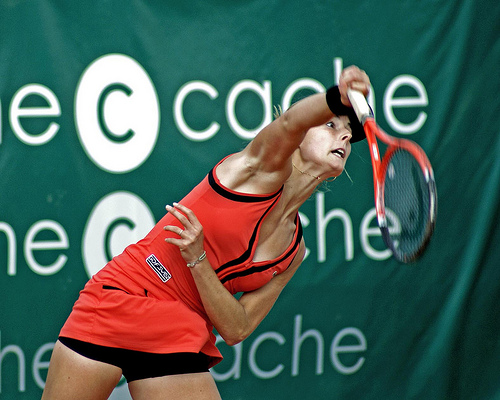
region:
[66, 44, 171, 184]
A white circle containing the letter c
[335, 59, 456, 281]
An orange tennis racket with a tan handle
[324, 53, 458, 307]
A woman holding a tennis racket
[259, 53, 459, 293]
A woman swinging a tennis racket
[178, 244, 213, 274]
A silver bracelet on a wrist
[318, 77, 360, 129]
A black sweatband on a wrist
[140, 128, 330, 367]
A tennis player wearing an orange shirt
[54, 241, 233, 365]
A tennis player wearing an orange skirt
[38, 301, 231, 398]
A tennis player wearing black shorts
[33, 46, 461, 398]
a tennis player playing tennis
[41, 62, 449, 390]
tennis player at the end of a stroke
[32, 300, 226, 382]
black shorts on a tennis player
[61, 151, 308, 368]
orange tennis shirt with black trim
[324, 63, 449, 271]
orange, black and white tennis racket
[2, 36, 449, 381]
green and white and gray advertising sign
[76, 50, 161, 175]
white circle with a green c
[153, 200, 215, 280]
left hand and wrist of tennis player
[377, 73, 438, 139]
white letter e on a green background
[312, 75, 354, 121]
black wristband on a right wrist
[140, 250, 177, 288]
logo of clothing brand on orange shirt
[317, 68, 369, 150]
the wrist band is black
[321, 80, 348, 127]
the wrist band is black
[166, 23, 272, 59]
the tarp is green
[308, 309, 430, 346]
the tarp is green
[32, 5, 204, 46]
the tarp is green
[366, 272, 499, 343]
the tarp is green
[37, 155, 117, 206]
the tarp is green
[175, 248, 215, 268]
Bracelet on woman's wrist.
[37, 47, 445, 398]
Woman playing tennis.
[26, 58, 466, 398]
Woman swinging a red tennis racket.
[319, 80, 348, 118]
Black sweatband on woman's wrist.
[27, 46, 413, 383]
Woman wearing a red tennis outfit.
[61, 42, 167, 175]
White circle with the letter C in the middle.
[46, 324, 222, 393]
Tight black shorts worn by a woman.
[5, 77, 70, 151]
Letter e written in white.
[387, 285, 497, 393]
Green backdrop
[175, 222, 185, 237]
Gold ring worn on the woman's ring finger.